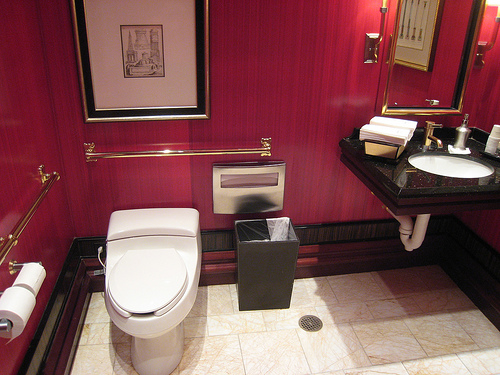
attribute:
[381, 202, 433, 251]
drainage pipe — white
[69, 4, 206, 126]
picture —  very nice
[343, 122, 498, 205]
counter top — black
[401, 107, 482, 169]
faucet — over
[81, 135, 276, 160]
rails — gold tone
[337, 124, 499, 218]
counter — black marble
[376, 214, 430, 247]
pipes — white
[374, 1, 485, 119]
mirror — golden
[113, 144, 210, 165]
racks — Gold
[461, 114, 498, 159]
cups — Small and white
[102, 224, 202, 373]
toilet — white, fancy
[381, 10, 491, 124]
mirror — framed in gold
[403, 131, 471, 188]
topped sink — marble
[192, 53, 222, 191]
framed — gold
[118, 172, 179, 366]
commode — white